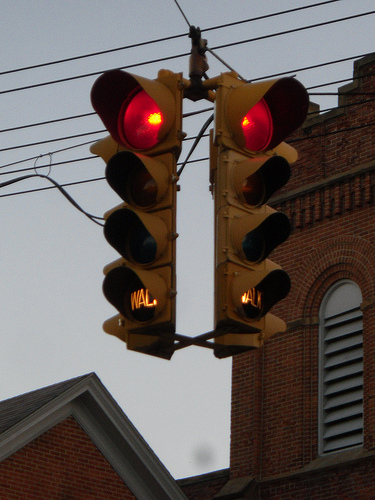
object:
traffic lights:
[89, 64, 182, 358]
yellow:
[115, 274, 163, 323]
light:
[120, 82, 171, 154]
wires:
[0, 0, 338, 80]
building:
[170, 54, 374, 500]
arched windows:
[317, 275, 364, 452]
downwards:
[317, 431, 365, 453]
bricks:
[363, 170, 374, 198]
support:
[154, 22, 237, 99]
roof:
[0, 364, 90, 434]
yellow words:
[126, 282, 158, 312]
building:
[0, 366, 190, 500]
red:
[235, 92, 272, 153]